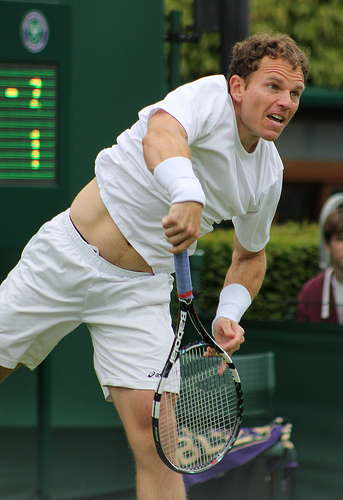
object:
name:
[169, 310, 187, 365]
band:
[65, 219, 114, 272]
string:
[72, 233, 100, 254]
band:
[211, 283, 251, 339]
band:
[153, 156, 206, 207]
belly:
[89, 201, 167, 275]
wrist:
[172, 181, 206, 201]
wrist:
[214, 310, 238, 323]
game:
[0, 1, 312, 499]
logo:
[148, 372, 160, 378]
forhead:
[260, 54, 305, 86]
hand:
[160, 188, 205, 255]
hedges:
[278, 223, 318, 273]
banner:
[177, 417, 298, 488]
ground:
[210, 448, 343, 500]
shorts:
[0, 208, 182, 403]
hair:
[229, 31, 260, 75]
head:
[227, 31, 310, 142]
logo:
[18, 8, 50, 54]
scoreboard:
[0, 59, 61, 190]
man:
[0, 30, 310, 499]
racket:
[151, 244, 245, 476]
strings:
[152, 385, 161, 411]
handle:
[173, 245, 192, 304]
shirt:
[94, 74, 285, 276]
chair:
[174, 351, 284, 500]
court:
[1, 442, 343, 500]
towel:
[238, 416, 286, 455]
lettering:
[176, 416, 294, 466]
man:
[294, 192, 343, 326]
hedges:
[192, 0, 328, 29]